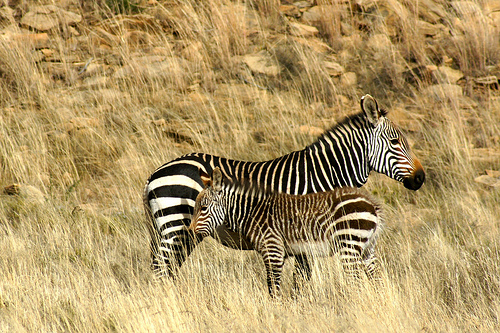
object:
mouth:
[400, 178, 423, 191]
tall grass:
[5, 9, 305, 144]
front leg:
[257, 239, 286, 302]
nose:
[415, 172, 426, 181]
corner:
[250, 80, 427, 203]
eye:
[391, 139, 400, 146]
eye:
[201, 206, 208, 212]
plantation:
[3, 1, 499, 331]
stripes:
[148, 174, 203, 192]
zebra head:
[358, 94, 426, 190]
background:
[0, 0, 497, 333]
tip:
[373, 281, 379, 287]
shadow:
[175, 194, 254, 269]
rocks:
[414, 62, 463, 82]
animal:
[188, 165, 386, 304]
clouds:
[144, 90, 434, 295]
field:
[0, 0, 499, 333]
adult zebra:
[142, 92, 425, 285]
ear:
[361, 94, 382, 126]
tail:
[141, 176, 156, 256]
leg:
[149, 212, 187, 282]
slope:
[5, 3, 484, 216]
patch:
[286, 242, 337, 255]